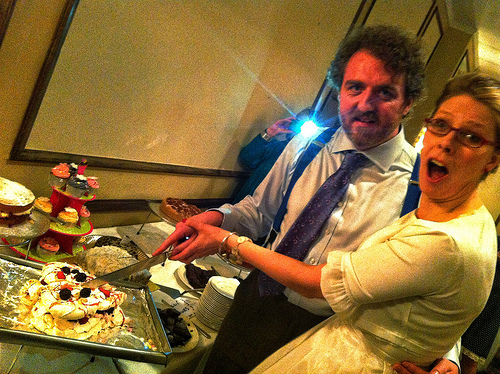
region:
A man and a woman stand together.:
[167, 20, 498, 372]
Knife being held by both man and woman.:
[73, 238, 220, 292]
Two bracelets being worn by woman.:
[210, 226, 256, 266]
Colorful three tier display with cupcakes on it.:
[36, 160, 98, 261]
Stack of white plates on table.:
[192, 275, 239, 337]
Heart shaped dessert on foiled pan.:
[27, 260, 129, 337]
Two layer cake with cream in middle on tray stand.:
[0, 175, 48, 260]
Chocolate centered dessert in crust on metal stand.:
[129, 198, 205, 246]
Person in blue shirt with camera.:
[218, 106, 316, 212]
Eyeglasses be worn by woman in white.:
[422, 113, 496, 158]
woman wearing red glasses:
[419, 115, 496, 150]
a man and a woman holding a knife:
[81, 208, 221, 286]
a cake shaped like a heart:
[41, 259, 126, 318]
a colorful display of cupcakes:
[5, 153, 99, 262]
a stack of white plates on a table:
[195, 273, 240, 331]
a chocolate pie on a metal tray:
[163, 191, 203, 221]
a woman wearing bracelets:
[218, 230, 249, 265]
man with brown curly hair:
[329, 26, 429, 148]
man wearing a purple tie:
[258, 153, 365, 295]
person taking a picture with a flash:
[272, 106, 319, 139]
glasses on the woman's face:
[421, 114, 498, 154]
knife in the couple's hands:
[80, 249, 177, 292]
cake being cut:
[21, 261, 128, 341]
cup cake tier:
[8, 157, 98, 261]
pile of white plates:
[190, 275, 247, 332]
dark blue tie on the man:
[258, 154, 370, 296]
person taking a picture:
[235, 107, 321, 207]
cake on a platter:
[0, 174, 54, 259]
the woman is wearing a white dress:
[237, 202, 497, 373]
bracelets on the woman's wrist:
[216, 227, 258, 267]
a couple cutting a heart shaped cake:
[19, 25, 499, 367]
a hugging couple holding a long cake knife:
[102, 26, 499, 372]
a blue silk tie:
[264, 149, 357, 293]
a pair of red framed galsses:
[421, 114, 493, 149]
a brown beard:
[334, 111, 401, 143]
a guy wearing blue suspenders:
[157, 28, 424, 372]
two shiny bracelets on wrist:
[218, 226, 251, 263]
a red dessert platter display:
[21, 163, 94, 260]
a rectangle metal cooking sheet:
[2, 253, 175, 358]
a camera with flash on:
[272, 109, 323, 139]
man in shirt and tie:
[154, 21, 429, 371]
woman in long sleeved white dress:
[168, 73, 498, 371]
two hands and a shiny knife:
[78, 207, 222, 299]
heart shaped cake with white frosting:
[31, 258, 125, 334]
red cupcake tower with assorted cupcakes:
[14, 157, 97, 260]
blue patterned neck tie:
[255, 153, 366, 299]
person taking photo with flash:
[233, 109, 316, 199]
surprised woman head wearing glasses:
[417, 74, 498, 199]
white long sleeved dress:
[244, 203, 493, 372]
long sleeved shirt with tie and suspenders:
[206, 127, 423, 315]